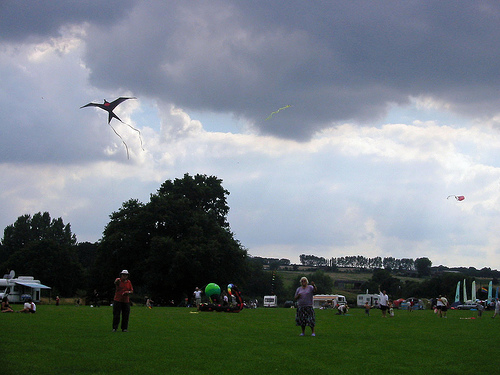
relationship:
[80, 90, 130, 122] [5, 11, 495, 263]
bird in sky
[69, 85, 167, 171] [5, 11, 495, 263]
kite in sky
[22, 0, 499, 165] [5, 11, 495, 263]
clouds in sky